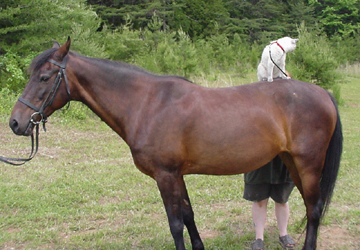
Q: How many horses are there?
A: One.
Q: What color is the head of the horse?
A: The head of the horse is brown.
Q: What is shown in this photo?
A: The head of a horse is shown in this photo.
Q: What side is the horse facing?
A: The horse is facing left.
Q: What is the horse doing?
A: The horse is standing still.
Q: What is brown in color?
A: The horse is brown in color.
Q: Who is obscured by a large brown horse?
A: A person is being obscured by a large brown horse.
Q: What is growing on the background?
A: There is vegetation growing in the background.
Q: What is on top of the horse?
A: A dog.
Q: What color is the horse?
A: Brown.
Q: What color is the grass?
A: Green.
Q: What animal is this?
A: Horse.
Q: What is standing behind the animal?
A: A person.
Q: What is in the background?
A: Trees.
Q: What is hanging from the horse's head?
A: Reins.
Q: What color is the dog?
A: White.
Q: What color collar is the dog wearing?
A: Red.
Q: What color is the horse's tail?
A: Black.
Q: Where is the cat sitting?
A: On the horse.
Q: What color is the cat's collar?
A: Red.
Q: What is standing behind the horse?
A: A person.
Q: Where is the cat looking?
A: Behind him.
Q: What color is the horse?
A: Brown.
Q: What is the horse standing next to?
A: A person.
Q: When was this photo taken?
A: Daytime.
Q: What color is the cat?
A: White.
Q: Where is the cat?
A: On the horses back.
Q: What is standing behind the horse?
A: A person.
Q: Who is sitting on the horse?
A: A cat.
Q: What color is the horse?
A: Brown.